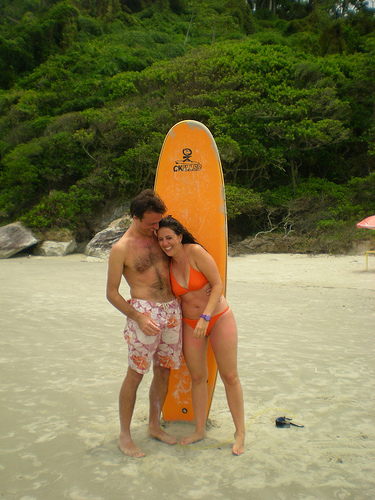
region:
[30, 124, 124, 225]
trees on the background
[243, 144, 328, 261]
trees on the background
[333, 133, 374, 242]
trees on the background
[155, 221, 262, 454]
this is a person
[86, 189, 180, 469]
this is a person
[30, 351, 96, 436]
sand on the beach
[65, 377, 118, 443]
sand on the beach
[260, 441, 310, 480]
sand on the beach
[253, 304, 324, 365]
sand on the beach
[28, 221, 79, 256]
this is a stone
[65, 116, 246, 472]
a couple standing in front of a surfboard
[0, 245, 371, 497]
sand covers the ground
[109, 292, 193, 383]
Hawaiian print swim trunks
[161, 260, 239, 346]
an orange bikini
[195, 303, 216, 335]
A purple watch on the woman's wrist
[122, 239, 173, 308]
the man has hair on his chest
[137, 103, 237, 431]
an orange surfboard standing in the sand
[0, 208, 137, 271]
rocks line the beach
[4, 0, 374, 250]
green trees in the background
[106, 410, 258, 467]
four bare feet in the sand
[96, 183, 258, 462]
a couple in the beach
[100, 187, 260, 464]
a couple laughs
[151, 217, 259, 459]
woman wears a bikini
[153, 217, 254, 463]
bikini of woman is orange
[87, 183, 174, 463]
man wears shorts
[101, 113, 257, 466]
a couple are in front a surfboard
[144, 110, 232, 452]
surfboard stand on the sand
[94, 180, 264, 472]
a couple is barefoot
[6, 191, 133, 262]
rocks on side of the beach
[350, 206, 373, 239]
part of a canopy of umbrella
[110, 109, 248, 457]
two people standing in front of surfboard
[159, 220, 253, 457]
woman wearing orange bikini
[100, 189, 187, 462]
man wearing flowered swim trunks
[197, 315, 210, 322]
purple watch on woman's wrist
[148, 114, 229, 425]
orangish yellow surfboard behind people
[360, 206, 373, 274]
umbrella on the right side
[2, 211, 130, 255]
group of three large rocks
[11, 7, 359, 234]
hill covered in foliage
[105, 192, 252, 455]
couple wearing swim clothes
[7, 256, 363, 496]
sand people are standing on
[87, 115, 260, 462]
a young couple at the beach with a surfboard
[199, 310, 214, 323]
purple watch on the lady's arm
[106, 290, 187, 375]
man's floral swimming trunks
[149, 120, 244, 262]
top of orange surfboard the couple are with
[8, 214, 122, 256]
several large rock at the edge of the sand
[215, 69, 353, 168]
very green leafy trees in the background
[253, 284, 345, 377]
white sand at the beach the couple are standing in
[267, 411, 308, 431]
a black object with a strap in the sand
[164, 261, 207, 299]
orange bikini top the woman is wearing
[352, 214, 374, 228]
edge of an orange umbrella